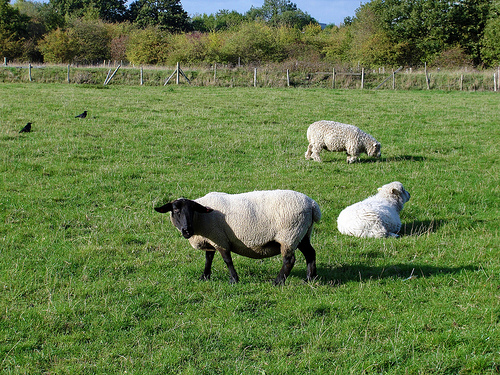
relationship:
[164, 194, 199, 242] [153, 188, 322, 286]
head of animal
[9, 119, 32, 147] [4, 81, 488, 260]
bird in grass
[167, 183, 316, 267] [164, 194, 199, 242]
animal has head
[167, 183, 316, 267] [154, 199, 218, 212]
animal has ears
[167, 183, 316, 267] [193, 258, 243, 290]
animal has legs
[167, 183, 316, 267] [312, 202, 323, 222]
animal has tail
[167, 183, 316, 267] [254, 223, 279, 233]
animal has wool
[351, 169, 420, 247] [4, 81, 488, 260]
animal on grass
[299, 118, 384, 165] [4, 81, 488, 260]
animal eating grass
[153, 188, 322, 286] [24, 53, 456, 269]
animal inside fenced area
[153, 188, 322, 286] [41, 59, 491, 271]
animal in field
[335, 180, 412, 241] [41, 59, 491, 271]
animal in field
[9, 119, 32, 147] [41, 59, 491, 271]
bird in field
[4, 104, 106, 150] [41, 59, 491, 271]
birds in field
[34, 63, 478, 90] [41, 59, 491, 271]
fence on field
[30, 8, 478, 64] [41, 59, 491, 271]
wooded area beyond field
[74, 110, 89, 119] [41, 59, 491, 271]
birds in field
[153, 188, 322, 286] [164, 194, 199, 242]
animal with head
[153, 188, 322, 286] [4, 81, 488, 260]
animal on grass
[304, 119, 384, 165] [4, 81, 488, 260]
animal eating grass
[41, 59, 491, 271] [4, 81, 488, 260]
field covered with grass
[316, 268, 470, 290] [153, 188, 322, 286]
shadow of animal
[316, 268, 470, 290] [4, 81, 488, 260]
shadow on grass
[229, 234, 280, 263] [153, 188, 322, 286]
belly of animal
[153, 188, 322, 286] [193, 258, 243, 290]
animal with legs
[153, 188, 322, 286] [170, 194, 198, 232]
animal with face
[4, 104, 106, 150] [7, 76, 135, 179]
birds on ground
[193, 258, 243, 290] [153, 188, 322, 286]
legs of animal